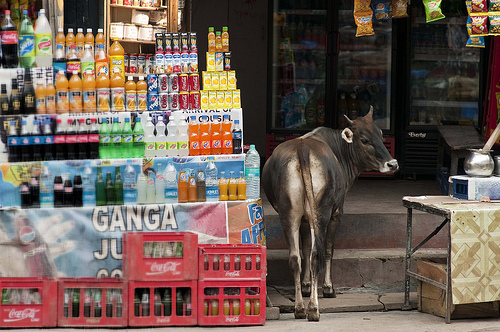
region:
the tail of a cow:
[287, 135, 352, 252]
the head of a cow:
[334, 100, 416, 180]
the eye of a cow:
[345, 130, 376, 150]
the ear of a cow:
[331, 118, 357, 148]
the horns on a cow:
[337, 80, 427, 132]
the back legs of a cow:
[286, 214, 356, 321]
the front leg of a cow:
[319, 191, 355, 293]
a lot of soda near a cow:
[31, 27, 290, 289]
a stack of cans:
[149, 68, 216, 115]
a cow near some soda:
[244, 97, 418, 294]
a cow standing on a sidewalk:
[274, 99, 410, 314]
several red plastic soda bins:
[0, 237, 263, 324]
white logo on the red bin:
[218, 268, 245, 276]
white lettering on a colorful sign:
[90, 207, 185, 231]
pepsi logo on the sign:
[13, 225, 35, 242]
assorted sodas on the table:
[6, 26, 260, 197]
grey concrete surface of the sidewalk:
[341, 313, 409, 330]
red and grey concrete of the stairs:
[348, 190, 400, 292]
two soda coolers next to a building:
[274, 3, 476, 175]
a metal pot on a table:
[463, 147, 496, 177]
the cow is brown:
[265, 93, 414, 295]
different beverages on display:
[15, 15, 267, 322]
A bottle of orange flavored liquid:
[206, 27, 216, 54]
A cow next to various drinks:
[261, 105, 397, 320]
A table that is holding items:
[401, 195, 498, 321]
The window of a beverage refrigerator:
[268, 3, 328, 134]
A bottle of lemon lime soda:
[99, 118, 111, 160]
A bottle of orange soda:
[190, 115, 200, 153]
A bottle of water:
[245, 143, 260, 197]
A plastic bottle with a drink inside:
[33, 6, 53, 65]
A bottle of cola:
[54, 117, 65, 157]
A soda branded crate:
[121, 231, 200, 282]